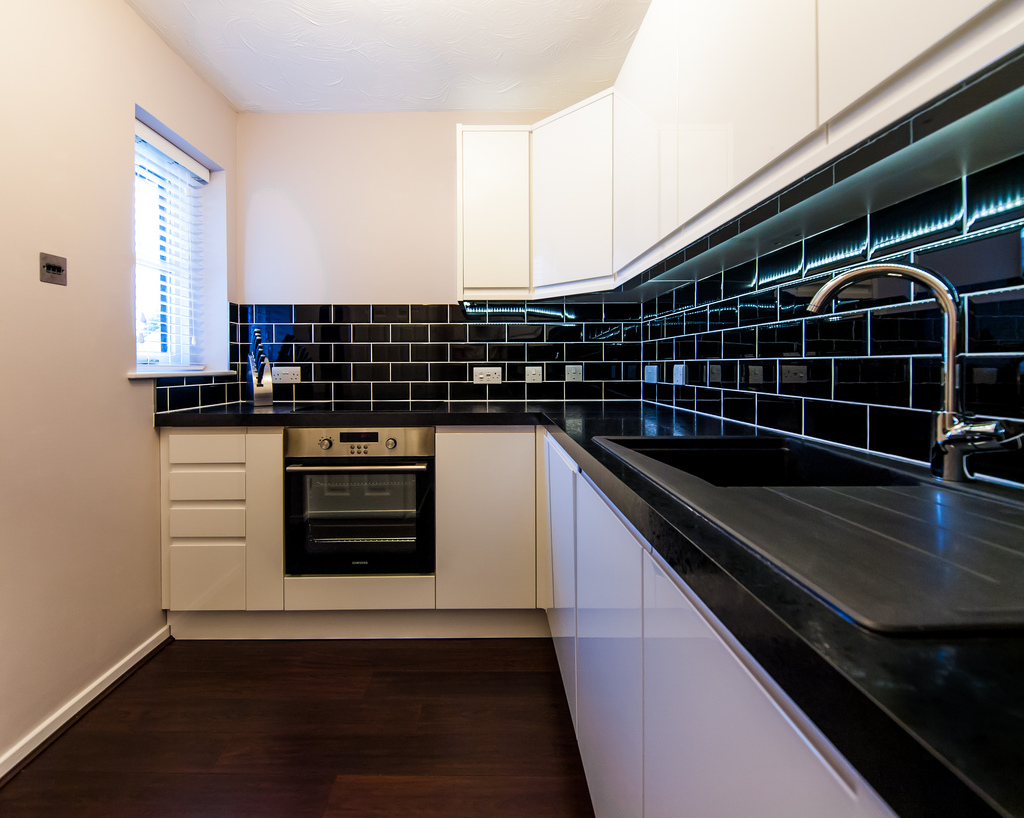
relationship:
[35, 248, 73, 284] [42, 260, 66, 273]
switch plate with switches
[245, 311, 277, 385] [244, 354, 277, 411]
knives in holder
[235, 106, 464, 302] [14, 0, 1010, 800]
wall on side of building